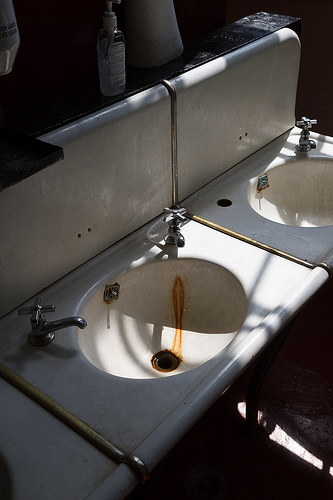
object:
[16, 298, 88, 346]
faucet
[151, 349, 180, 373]
drain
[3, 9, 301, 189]
top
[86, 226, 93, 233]
hole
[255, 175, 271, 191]
metal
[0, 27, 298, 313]
back splash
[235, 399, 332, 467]
sunlight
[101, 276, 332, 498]
ground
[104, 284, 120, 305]
grate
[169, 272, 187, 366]
stain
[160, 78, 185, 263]
metal strip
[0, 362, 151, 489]
metal strip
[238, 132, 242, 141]
holes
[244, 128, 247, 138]
holes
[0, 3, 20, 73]
sitting products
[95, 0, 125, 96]
bottle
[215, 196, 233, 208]
hole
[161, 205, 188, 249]
faucet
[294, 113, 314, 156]
handle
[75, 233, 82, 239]
hole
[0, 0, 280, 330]
wall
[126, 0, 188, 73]
paper towels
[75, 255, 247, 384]
bowl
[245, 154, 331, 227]
bowl